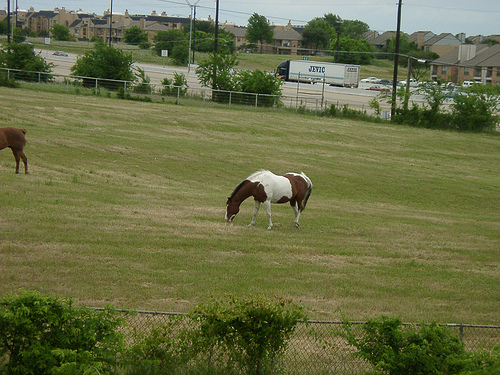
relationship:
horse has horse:
[223, 167, 313, 231] [223, 167, 313, 231]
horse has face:
[217, 164, 317, 230] [226, 195, 237, 227]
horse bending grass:
[217, 164, 317, 230] [0, 82, 500, 373]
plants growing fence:
[1, 290, 498, 372] [6, 294, 498, 374]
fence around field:
[301, 329, 336, 364] [303, 296, 345, 365]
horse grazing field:
[223, 167, 313, 231] [234, 227, 334, 262]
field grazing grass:
[1, 79, 493, 324] [54, 106, 172, 175]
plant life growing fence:
[6, 297, 498, 374] [6, 294, 498, 374]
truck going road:
[274, 57, 362, 89] [0, 49, 500, 133]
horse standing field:
[217, 164, 317, 230] [1, 79, 493, 324]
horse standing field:
[223, 167, 313, 231] [73, 104, 188, 256]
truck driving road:
[274, 57, 362, 89] [36, 42, 499, 127]